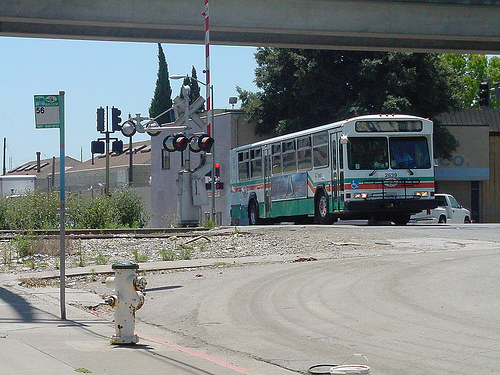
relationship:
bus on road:
[229, 113, 437, 226] [0, 225, 498, 374]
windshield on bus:
[342, 133, 429, 170] [216, 101, 494, 260]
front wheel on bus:
[315, 191, 332, 223] [229, 113, 437, 226]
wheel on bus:
[246, 197, 260, 227] [229, 113, 437, 226]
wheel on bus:
[313, 190, 333, 221] [229, 113, 437, 226]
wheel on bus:
[440, 217, 446, 224] [229, 113, 437, 226]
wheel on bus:
[464, 215, 472, 225] [229, 113, 437, 226]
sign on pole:
[34, 94, 59, 128] [53, 132, 77, 327]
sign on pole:
[173, 94, 210, 131] [208, 189, 218, 234]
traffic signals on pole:
[95, 104, 125, 135] [57, 129, 67, 322]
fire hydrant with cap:
[104, 260, 148, 344] [110, 257, 139, 272]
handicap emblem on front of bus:
[348, 176, 364, 193] [219, 72, 461, 250]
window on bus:
[278, 142, 298, 170] [316, 120, 446, 220]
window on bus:
[295, 139, 313, 169] [316, 120, 446, 220]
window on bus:
[309, 132, 330, 164] [316, 120, 446, 220]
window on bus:
[248, 150, 267, 179] [316, 120, 446, 220]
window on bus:
[237, 151, 249, 180] [316, 120, 446, 220]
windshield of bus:
[347, 136, 432, 170] [229, 113, 437, 226]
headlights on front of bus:
[352, 191, 368, 198] [229, 113, 437, 226]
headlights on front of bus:
[414, 191, 429, 196] [229, 113, 437, 226]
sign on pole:
[34, 93, 59, 129] [32, 90, 72, 318]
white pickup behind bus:
[392, 193, 498, 231] [229, 113, 437, 226]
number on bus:
[386, 174, 398, 181] [222, 107, 440, 229]